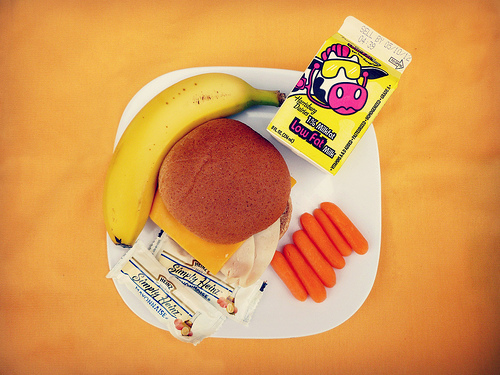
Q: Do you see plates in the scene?
A: Yes, there is a plate.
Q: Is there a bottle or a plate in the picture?
A: Yes, there is a plate.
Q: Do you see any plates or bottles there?
A: Yes, there is a plate.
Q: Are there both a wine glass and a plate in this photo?
A: No, there is a plate but no wine glasses.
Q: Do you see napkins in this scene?
A: No, there are no napkins.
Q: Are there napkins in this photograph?
A: No, there are no napkins.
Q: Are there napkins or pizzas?
A: No, there are no napkins or pizzas.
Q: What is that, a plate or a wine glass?
A: That is a plate.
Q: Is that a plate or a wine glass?
A: That is a plate.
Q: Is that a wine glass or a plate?
A: That is a plate.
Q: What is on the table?
A: The plate is on the table.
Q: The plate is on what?
A: The plate is on the table.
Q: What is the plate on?
A: The plate is on the table.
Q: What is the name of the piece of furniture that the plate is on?
A: The piece of furniture is a table.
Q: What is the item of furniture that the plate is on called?
A: The piece of furniture is a table.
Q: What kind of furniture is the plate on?
A: The plate is on the table.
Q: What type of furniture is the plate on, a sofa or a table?
A: The plate is on a table.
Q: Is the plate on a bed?
A: No, the plate is on a table.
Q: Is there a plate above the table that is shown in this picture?
A: Yes, there is a plate above the table.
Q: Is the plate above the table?
A: Yes, the plate is above the table.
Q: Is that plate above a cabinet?
A: No, the plate is above the table.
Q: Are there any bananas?
A: Yes, there is a banana.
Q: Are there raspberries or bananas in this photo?
A: Yes, there is a banana.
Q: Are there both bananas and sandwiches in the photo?
A: Yes, there are both a banana and a sandwich.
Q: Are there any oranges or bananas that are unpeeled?
A: Yes, the banana is unpeeled.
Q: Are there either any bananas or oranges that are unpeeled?
A: Yes, the banana is unpeeled.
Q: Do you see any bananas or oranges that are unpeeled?
A: Yes, the banana is unpeeled.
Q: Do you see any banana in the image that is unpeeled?
A: Yes, there is an unpeeled banana.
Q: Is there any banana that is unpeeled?
A: Yes, there is a banana that is unpeeled.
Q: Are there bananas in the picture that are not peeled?
A: Yes, there is a unpeeled banana.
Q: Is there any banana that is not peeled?
A: Yes, there is a unpeeled banana.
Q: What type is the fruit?
A: The fruit is a banana.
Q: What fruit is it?
A: The fruit is a banana.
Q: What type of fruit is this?
A: This is a banana.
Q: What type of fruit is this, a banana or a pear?
A: This is a banana.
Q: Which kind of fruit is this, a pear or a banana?
A: This is a banana.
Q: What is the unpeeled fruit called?
A: The fruit is a banana.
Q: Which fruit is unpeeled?
A: The fruit is a banana.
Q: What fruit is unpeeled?
A: The fruit is a banana.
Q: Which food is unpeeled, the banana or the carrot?
A: The banana is unpeeled.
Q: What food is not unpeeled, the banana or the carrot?
A: The carrot is not unpeeled.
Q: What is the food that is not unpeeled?
A: The food is a carrot.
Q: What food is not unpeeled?
A: The food is a carrot.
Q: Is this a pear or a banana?
A: This is a banana.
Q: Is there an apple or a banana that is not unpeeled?
A: No, there is a banana but it is unpeeled.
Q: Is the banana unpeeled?
A: Yes, the banana is unpeeled.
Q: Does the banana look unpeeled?
A: Yes, the banana is unpeeled.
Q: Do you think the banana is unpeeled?
A: Yes, the banana is unpeeled.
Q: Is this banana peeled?
A: No, the banana is unpeeled.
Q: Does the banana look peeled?
A: No, the banana is unpeeled.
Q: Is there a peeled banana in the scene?
A: No, there is a banana but it is unpeeled.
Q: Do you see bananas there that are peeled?
A: No, there is a banana but it is unpeeled.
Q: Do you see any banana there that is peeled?
A: No, there is a banana but it is unpeeled.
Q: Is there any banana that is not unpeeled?
A: No, there is a banana but it is unpeeled.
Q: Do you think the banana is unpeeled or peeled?
A: The banana is unpeeled.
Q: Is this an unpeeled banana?
A: Yes, this is an unpeeled banana.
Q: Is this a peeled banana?
A: No, this is an unpeeled banana.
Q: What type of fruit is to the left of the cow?
A: The fruit is a banana.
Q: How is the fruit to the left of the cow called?
A: The fruit is a banana.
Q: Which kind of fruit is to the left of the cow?
A: The fruit is a banana.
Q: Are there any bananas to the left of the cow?
A: Yes, there is a banana to the left of the cow.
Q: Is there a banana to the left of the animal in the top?
A: Yes, there is a banana to the left of the cow.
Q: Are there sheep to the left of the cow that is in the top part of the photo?
A: No, there is a banana to the left of the cow.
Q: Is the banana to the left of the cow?
A: Yes, the banana is to the left of the cow.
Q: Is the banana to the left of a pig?
A: No, the banana is to the left of the cow.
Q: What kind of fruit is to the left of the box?
A: The fruit is a banana.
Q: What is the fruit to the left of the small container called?
A: The fruit is a banana.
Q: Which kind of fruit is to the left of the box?
A: The fruit is a banana.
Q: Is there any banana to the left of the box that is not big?
A: Yes, there is a banana to the left of the box.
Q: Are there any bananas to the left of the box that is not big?
A: Yes, there is a banana to the left of the box.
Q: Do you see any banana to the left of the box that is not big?
A: Yes, there is a banana to the left of the box.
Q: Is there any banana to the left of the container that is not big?
A: Yes, there is a banana to the left of the box.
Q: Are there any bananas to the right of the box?
A: No, the banana is to the left of the box.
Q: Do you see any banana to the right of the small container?
A: No, the banana is to the left of the box.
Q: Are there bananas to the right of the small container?
A: No, the banana is to the left of the box.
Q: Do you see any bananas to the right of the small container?
A: No, the banana is to the left of the box.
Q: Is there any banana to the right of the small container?
A: No, the banana is to the left of the box.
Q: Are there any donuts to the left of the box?
A: No, there is a banana to the left of the box.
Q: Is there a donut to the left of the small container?
A: No, there is a banana to the left of the box.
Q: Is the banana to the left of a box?
A: Yes, the banana is to the left of a box.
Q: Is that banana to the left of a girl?
A: No, the banana is to the left of a box.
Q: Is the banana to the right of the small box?
A: No, the banana is to the left of the box.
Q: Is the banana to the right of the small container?
A: No, the banana is to the left of the box.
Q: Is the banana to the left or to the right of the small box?
A: The banana is to the left of the box.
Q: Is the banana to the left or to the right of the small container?
A: The banana is to the left of the box.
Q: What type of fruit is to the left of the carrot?
A: The fruit is a banana.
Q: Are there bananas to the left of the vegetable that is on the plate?
A: Yes, there is a banana to the left of the carrot.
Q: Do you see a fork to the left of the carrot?
A: No, there is a banana to the left of the carrot.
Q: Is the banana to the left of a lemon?
A: No, the banana is to the left of a carrot.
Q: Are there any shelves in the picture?
A: No, there are no shelves.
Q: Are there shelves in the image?
A: No, there are no shelves.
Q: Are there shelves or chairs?
A: No, there are no shelves or chairs.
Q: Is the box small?
A: Yes, the box is small.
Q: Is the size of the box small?
A: Yes, the box is small.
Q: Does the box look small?
A: Yes, the box is small.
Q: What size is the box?
A: The box is small.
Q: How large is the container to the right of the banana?
A: The box is small.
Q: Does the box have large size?
A: No, the box is small.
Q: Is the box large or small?
A: The box is small.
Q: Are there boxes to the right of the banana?
A: Yes, there is a box to the right of the banana.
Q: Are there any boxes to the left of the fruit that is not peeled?
A: No, the box is to the right of the banana.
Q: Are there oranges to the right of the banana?
A: No, there is a box to the right of the banana.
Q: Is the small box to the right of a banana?
A: Yes, the box is to the right of a banana.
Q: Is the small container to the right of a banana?
A: Yes, the box is to the right of a banana.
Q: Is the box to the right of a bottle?
A: No, the box is to the right of a banana.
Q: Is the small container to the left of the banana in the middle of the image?
A: No, the box is to the right of the banana.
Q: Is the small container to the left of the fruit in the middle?
A: No, the box is to the right of the banana.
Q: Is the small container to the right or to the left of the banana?
A: The box is to the right of the banana.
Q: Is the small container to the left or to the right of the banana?
A: The box is to the right of the banana.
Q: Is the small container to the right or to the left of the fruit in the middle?
A: The box is to the right of the banana.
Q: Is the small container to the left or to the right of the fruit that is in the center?
A: The box is to the right of the banana.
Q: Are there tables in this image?
A: Yes, there is a table.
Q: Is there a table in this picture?
A: Yes, there is a table.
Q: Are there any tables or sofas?
A: Yes, there is a table.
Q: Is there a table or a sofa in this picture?
A: Yes, there is a table.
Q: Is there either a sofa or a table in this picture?
A: Yes, there is a table.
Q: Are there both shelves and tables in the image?
A: No, there is a table but no shelves.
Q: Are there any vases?
A: No, there are no vases.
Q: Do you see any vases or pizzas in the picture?
A: No, there are no vases or pizzas.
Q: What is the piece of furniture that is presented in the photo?
A: The piece of furniture is a table.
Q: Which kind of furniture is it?
A: The piece of furniture is a table.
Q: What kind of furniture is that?
A: That is a table.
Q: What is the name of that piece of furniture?
A: That is a table.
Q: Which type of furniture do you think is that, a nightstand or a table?
A: That is a table.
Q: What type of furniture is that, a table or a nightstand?
A: That is a table.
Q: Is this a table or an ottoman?
A: This is a table.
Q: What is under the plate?
A: The table is under the plate.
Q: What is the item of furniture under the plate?
A: The piece of furniture is a table.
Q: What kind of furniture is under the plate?
A: The piece of furniture is a table.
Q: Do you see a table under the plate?
A: Yes, there is a table under the plate.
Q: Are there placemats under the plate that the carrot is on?
A: No, there is a table under the plate.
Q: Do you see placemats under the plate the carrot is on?
A: No, there is a table under the plate.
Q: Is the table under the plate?
A: Yes, the table is under the plate.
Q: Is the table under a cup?
A: No, the table is under the plate.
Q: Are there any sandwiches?
A: Yes, there is a sandwich.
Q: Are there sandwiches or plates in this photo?
A: Yes, there is a sandwich.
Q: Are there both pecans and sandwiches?
A: No, there is a sandwich but no pecans.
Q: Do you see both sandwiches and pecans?
A: No, there is a sandwich but no pecans.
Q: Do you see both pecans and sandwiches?
A: No, there is a sandwich but no pecans.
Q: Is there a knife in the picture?
A: No, there are no knives.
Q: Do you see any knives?
A: No, there are no knives.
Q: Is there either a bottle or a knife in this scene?
A: No, there are no knives or bottles.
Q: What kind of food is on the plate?
A: The food is a sandwich.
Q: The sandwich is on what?
A: The sandwich is on the plate.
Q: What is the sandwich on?
A: The sandwich is on the plate.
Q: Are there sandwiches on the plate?
A: Yes, there is a sandwich on the plate.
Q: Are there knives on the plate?
A: No, there is a sandwich on the plate.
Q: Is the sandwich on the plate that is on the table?
A: Yes, the sandwich is on the plate.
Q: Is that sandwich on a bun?
A: No, the sandwich is on the plate.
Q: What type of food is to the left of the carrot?
A: The food is a sandwich.